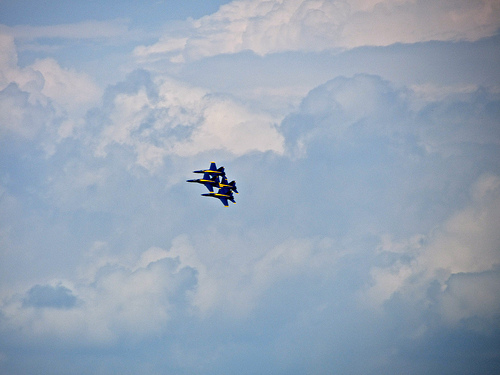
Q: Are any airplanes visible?
A: Yes, there is an airplane.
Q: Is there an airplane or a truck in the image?
A: Yes, there is an airplane.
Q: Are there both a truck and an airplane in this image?
A: No, there is an airplane but no trucks.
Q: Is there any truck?
A: No, there are no trucks.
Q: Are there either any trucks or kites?
A: No, there are no trucks or kites.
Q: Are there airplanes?
A: Yes, there is an airplane.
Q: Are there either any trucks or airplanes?
A: Yes, there is an airplane.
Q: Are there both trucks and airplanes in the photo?
A: No, there is an airplane but no trucks.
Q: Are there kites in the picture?
A: No, there are no kites.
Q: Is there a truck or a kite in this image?
A: No, there are no kites or trucks.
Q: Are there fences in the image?
A: No, there are no fences.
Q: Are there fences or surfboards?
A: No, there are no fences or surfboards.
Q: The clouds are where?
A: The clouds are in the sky.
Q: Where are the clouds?
A: The clouds are in the sky.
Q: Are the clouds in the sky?
A: Yes, the clouds are in the sky.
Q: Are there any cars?
A: No, there are no cars.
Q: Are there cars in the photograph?
A: No, there are no cars.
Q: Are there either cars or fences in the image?
A: No, there are no cars or fences.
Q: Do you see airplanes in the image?
A: Yes, there are airplanes.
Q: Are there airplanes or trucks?
A: Yes, there are airplanes.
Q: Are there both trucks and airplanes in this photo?
A: No, there are airplanes but no trucks.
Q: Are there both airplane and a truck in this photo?
A: No, there are airplanes but no trucks.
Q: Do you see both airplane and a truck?
A: No, there are airplanes but no trucks.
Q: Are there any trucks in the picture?
A: No, there are no trucks.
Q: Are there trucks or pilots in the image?
A: No, there are no trucks or pilots.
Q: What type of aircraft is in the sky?
A: The aircraft is airplanes.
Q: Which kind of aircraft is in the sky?
A: The aircraft is airplanes.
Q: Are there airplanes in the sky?
A: Yes, there are airplanes in the sky.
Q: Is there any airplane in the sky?
A: Yes, there are airplanes in the sky.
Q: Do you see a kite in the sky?
A: No, there are airplanes in the sky.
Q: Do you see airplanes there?
A: Yes, there is an airplane.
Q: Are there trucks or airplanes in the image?
A: Yes, there is an airplane.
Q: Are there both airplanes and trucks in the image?
A: No, there is an airplane but no trucks.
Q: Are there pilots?
A: No, there are no pilots.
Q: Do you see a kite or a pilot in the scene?
A: No, there are no pilots or kites.